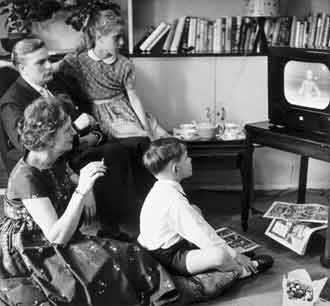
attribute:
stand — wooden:
[225, 112, 326, 247]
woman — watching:
[13, 92, 141, 305]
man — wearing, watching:
[20, 43, 76, 115]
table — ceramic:
[71, 133, 259, 234]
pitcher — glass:
[191, 112, 223, 144]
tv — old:
[263, 42, 329, 141]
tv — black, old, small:
[263, 46, 329, 135]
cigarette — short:
[100, 157, 104, 161]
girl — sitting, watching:
[1, 7, 177, 139]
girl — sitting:
[63, 9, 183, 141]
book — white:
[140, 21, 166, 52]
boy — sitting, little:
[132, 138, 267, 278]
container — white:
[282, 271, 325, 304]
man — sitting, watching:
[8, 39, 132, 244]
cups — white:
[167, 115, 245, 141]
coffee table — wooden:
[192, 137, 257, 227]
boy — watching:
[136, 136, 259, 278]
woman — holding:
[0, 93, 176, 302]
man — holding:
[5, 31, 102, 181]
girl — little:
[69, 5, 170, 138]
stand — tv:
[234, 116, 329, 261]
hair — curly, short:
[16, 99, 80, 155]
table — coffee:
[199, 144, 250, 156]